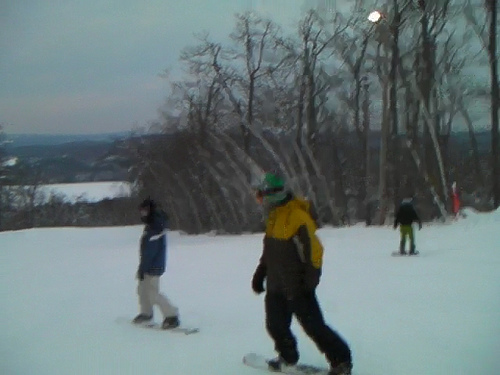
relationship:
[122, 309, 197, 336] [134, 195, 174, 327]
skis on man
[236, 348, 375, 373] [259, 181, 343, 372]
snowboard on man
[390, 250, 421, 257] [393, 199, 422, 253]
snowboard on person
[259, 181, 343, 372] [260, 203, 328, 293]
man with jacket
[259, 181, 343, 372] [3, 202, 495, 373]
man on snow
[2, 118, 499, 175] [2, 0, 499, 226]
mountains behind trees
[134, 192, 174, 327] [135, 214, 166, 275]
man in jacket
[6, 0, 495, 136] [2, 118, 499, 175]
sky above mountains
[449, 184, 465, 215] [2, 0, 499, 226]
sign by trees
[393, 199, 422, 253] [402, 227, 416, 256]
person in green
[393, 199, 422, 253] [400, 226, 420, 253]
person in pants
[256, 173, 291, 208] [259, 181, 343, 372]
helmet on man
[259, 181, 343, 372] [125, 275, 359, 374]
man have leg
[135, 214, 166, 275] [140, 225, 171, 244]
jacket has stripe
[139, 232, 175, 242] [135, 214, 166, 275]
stripe across jacket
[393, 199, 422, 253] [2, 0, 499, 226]
person nearing trees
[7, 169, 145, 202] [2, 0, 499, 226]
snow beyond trees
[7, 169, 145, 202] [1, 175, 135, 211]
snow in area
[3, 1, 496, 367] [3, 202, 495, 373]
place has snow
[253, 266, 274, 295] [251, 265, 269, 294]
glove on hand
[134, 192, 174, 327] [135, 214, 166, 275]
man wears jacket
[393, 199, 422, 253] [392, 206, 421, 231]
person wears jacket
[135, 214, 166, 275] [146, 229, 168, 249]
jacket has strip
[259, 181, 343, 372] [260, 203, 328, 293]
man wearing jacket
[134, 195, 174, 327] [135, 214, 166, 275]
man wearing jacket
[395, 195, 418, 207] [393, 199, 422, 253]
hat on person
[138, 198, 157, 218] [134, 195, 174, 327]
hat on man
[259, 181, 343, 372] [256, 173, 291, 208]
man wears helmet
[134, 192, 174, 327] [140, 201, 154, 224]
man wearing mask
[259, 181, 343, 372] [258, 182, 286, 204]
man wearing mask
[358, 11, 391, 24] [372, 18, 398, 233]
light on pole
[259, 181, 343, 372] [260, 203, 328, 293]
man wears jacket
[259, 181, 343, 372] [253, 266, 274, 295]
man wearing glove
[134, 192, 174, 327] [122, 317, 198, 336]
man on skis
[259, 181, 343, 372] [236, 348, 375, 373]
man on snowboard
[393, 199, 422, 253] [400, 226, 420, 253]
person wears pants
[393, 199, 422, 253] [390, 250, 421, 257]
person on snowboard